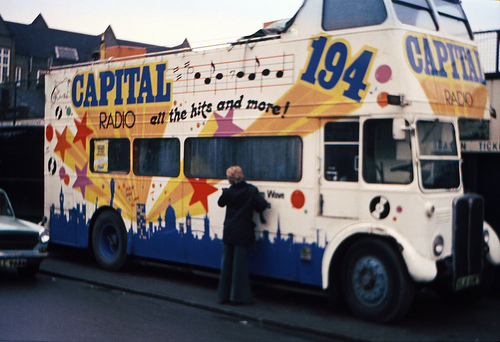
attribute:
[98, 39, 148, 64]
suitcase — brown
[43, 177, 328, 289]
buildings — blue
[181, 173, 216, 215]
star — red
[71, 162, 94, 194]
star — purple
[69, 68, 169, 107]
letters — blue